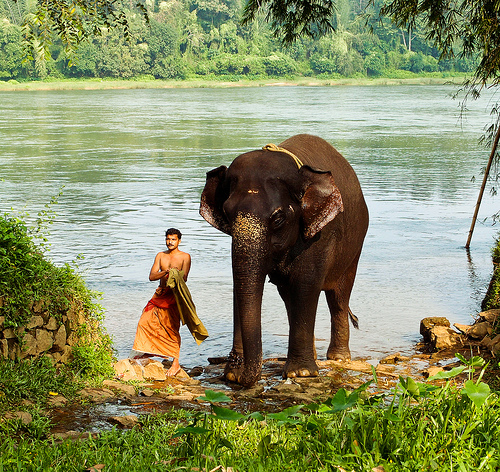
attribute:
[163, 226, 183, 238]
hair — black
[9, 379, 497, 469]
grass — lush, green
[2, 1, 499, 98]
forest — green 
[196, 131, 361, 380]
elephant — big, brown, wet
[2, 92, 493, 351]
river — middle-ground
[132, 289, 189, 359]
cloth — orange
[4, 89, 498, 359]
water — still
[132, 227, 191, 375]
man — dark haired